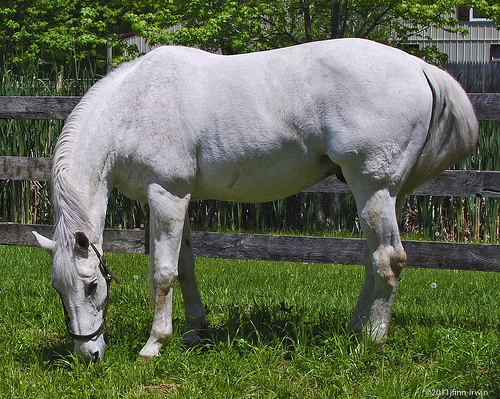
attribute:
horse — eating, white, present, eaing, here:
[46, 20, 482, 346]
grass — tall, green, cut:
[20, 329, 171, 389]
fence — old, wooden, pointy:
[14, 87, 52, 301]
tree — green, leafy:
[95, 22, 202, 63]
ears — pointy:
[25, 231, 104, 255]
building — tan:
[398, 8, 496, 90]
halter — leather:
[60, 313, 139, 347]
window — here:
[463, 4, 497, 47]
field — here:
[403, 201, 494, 289]